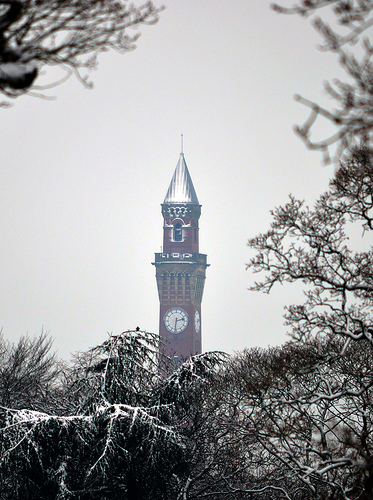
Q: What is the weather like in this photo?
A: It is cloudy.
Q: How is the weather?
A: It is cloudy.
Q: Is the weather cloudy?
A: Yes, it is cloudy.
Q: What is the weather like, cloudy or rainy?
A: It is cloudy.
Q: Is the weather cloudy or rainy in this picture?
A: It is cloudy.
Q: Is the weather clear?
A: No, it is cloudy.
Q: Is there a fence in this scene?
A: No, there are no fences.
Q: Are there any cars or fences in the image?
A: No, there are no fences or cars.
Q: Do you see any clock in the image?
A: Yes, there is a clock.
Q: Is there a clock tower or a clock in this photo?
A: Yes, there is a clock.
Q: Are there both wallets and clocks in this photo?
A: No, there is a clock but no wallets.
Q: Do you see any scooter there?
A: No, there are no scooters.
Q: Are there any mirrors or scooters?
A: No, there are no scooters or mirrors.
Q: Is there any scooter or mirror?
A: No, there are no scooters or mirrors.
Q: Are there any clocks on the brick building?
A: Yes, there is a clock on the building.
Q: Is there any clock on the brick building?
A: Yes, there is a clock on the building.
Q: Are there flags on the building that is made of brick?
A: No, there is a clock on the building.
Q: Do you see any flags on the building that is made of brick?
A: No, there is a clock on the building.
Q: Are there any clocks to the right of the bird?
A: Yes, there is a clock to the right of the bird.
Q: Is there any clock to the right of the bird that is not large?
A: Yes, there is a clock to the right of the bird.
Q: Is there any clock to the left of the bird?
A: No, the clock is to the right of the bird.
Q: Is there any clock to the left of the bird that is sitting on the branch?
A: No, the clock is to the right of the bird.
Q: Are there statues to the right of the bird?
A: No, there is a clock to the right of the bird.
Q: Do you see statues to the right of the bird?
A: No, there is a clock to the right of the bird.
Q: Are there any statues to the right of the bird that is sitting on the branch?
A: No, there is a clock to the right of the bird.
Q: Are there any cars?
A: No, there are no cars.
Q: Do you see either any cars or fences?
A: No, there are no cars or fences.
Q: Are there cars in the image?
A: No, there are no cars.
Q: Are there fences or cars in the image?
A: No, there are no cars or fences.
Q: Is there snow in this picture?
A: Yes, there is snow.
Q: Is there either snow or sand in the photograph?
A: Yes, there is snow.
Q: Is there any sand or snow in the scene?
A: Yes, there is snow.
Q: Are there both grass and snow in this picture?
A: No, there is snow but no grass.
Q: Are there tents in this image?
A: No, there are no tents.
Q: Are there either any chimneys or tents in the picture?
A: No, there are no tents or chimneys.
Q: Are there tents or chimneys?
A: No, there are no tents or chimneys.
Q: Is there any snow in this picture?
A: Yes, there is snow.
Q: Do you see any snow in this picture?
A: Yes, there is snow.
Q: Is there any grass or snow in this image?
A: Yes, there is snow.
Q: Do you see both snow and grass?
A: No, there is snow but no grass.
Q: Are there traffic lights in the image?
A: No, there are no traffic lights.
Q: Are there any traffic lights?
A: No, there are no traffic lights.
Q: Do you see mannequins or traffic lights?
A: No, there are no traffic lights or mannequins.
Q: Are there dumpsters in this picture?
A: No, there are no dumpsters.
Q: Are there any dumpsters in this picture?
A: No, there are no dumpsters.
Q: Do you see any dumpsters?
A: No, there are no dumpsters.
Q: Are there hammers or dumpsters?
A: No, there are no dumpsters or hammers.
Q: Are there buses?
A: No, there are no buses.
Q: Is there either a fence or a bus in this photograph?
A: No, there are no buses or fences.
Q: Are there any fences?
A: No, there are no fences.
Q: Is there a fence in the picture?
A: No, there are no fences.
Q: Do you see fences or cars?
A: No, there are no fences or cars.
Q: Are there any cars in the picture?
A: No, there are no cars.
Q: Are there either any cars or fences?
A: No, there are no cars or fences.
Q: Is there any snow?
A: Yes, there is snow.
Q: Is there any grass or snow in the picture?
A: Yes, there is snow.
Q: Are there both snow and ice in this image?
A: No, there is snow but no ice.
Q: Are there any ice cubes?
A: No, there are no ice cubes.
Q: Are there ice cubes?
A: No, there are no ice cubes.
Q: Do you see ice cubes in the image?
A: No, there are no ice cubes.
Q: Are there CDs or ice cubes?
A: No, there are no ice cubes or cds.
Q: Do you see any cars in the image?
A: No, there are no cars.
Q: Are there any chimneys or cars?
A: No, there are no cars or chimneys.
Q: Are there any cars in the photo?
A: No, there are no cars.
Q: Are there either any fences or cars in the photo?
A: No, there are no cars or fences.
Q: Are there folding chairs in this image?
A: No, there are no folding chairs.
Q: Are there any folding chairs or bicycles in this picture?
A: No, there are no folding chairs or bicycles.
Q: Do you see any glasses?
A: No, there are no glasses.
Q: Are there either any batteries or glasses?
A: No, there are no glasses or batteries.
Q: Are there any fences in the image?
A: No, there are no fences.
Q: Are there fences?
A: No, there are no fences.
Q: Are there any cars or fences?
A: No, there are no fences or cars.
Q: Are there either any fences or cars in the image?
A: No, there are no fences or cars.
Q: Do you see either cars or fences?
A: No, there are no fences or cars.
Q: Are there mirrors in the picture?
A: No, there are no mirrors.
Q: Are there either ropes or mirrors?
A: No, there are no mirrors or ropes.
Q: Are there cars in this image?
A: No, there are no cars.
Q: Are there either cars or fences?
A: No, there are no cars or fences.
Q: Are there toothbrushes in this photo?
A: No, there are no toothbrushes.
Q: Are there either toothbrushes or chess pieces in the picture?
A: No, there are no toothbrushes or chess pieces.